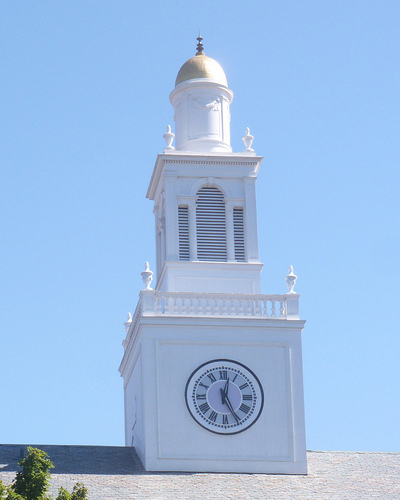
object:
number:
[231, 373, 238, 384]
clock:
[183, 356, 264, 437]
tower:
[119, 34, 311, 475]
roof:
[142, 148, 261, 203]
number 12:
[219, 370, 227, 381]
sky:
[0, 0, 399, 454]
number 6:
[223, 414, 229, 424]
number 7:
[206, 410, 221, 423]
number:
[196, 393, 206, 401]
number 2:
[239, 383, 249, 391]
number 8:
[198, 400, 212, 414]